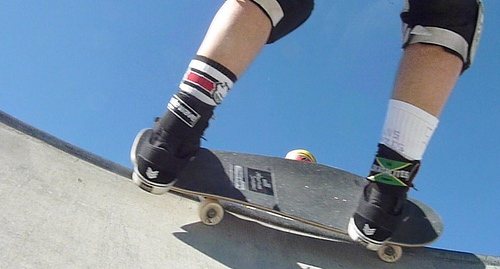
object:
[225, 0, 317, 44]
kneepads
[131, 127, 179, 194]
sole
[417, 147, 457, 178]
ground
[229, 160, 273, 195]
label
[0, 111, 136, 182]
metal edge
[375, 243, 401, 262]
wheel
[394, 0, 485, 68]
pad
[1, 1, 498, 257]
sky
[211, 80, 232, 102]
logo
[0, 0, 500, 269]
skateboarding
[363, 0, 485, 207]
leg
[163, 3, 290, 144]
leg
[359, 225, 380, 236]
logo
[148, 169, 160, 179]
logo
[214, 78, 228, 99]
logo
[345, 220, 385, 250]
heel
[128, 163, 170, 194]
heel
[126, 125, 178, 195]
shoe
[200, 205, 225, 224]
wheel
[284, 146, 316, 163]
object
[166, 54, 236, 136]
sock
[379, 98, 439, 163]
sock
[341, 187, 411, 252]
shoe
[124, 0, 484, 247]
man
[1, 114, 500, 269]
ramp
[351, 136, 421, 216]
brace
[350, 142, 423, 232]
ankle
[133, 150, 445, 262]
board